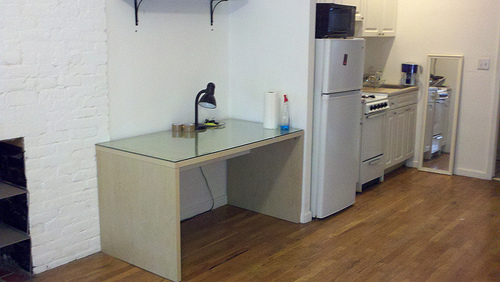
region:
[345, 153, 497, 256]
a hard wood floor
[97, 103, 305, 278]
a white desk in the corner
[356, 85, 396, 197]
a white gas stove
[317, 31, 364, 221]
a white refrigerator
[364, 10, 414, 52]
a cabinet on the wall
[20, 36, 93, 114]
a white brick wall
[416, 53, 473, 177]
a mirror against the wal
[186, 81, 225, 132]
a lamp on a desk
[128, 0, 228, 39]
black shelf brackets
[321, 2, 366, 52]
a tv on the refrigerator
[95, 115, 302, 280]
Wood and glass rectangular desk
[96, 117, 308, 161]
Clear rectangular glass top for desk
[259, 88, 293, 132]
Roll of paper towels and bottle of glass cleaner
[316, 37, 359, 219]
white refrigerator with freezer door on top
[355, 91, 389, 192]
White oven and range top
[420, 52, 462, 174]
Rectangular mirror leaning against wall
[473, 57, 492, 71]
Double switch electrical receptacle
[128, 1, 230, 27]
Two black metal shelf brackets attached to wall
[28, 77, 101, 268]
Brick wall painted white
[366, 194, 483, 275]
Brown wood floor boards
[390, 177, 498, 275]
Wooden Floors on the ground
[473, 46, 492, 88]
Light Switch on wall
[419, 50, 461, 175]
Full body mirror standing against wall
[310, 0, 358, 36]
Black microwave in kitchen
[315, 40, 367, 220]
White refridgerator standing up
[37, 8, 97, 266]
White painted brick wall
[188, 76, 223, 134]
Reading lamp on desk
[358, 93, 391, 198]
White stove in kitchen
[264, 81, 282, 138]
Paper towel on a roll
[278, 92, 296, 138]
Glass and Window cleaner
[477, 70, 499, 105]
Coffee maker on the kitchen counter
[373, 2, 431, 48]
Microwave on top of refridgerater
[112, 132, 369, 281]
Desk next to refridgerater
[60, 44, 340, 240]
a light on a table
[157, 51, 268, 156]
a lamp on glass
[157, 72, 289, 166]
a light on a glass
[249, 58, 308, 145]
a roll of paper towels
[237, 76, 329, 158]
a roll paper towels on a table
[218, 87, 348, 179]
a glass cleaner on a table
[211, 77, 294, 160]
paper towels and cleaner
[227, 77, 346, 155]
a bottle of cleaner